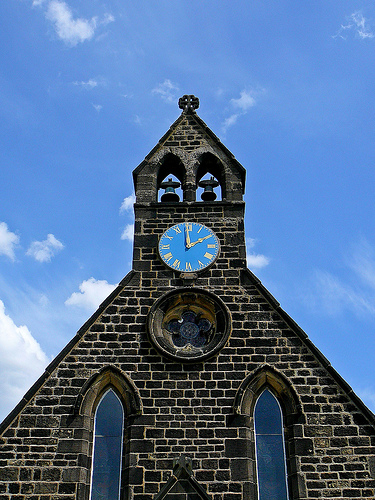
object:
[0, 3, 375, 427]
sky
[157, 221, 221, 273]
clock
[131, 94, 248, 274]
tower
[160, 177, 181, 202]
bell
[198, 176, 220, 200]
bell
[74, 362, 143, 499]
window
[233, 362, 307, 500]
window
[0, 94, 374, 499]
building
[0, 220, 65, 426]
cloud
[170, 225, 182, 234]
roman numeral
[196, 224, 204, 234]
roman numeral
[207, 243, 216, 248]
roman numeral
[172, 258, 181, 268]
roman numeral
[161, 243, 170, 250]
roman numeral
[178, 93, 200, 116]
steeple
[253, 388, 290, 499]
glass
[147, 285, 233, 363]
decoration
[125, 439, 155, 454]
brick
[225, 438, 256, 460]
brick